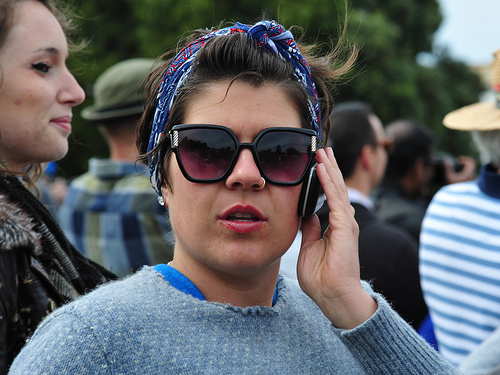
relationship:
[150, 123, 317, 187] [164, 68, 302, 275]
sunglasses on face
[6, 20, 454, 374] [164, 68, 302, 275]
woman has face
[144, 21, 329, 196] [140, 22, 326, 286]
bandana wrapped around head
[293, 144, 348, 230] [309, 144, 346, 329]
cellphone in a woman's hand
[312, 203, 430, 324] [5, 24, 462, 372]
suit coat on man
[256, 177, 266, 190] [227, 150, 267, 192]
nose ring in nose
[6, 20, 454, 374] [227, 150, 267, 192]
woman has nose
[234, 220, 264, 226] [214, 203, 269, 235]
lipstick applied to lips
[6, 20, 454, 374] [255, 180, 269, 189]
woman sporting nose ring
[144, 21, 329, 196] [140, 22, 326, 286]
bandana around head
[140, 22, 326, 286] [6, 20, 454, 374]
head of woman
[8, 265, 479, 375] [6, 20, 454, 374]
sweater on woman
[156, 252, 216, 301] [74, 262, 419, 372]
tshirt under sweater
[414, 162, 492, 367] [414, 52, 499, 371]
shirt on man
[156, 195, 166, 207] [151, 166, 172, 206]
earring on woman's ear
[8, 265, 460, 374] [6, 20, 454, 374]
sweater on woman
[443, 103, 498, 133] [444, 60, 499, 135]
brim of hat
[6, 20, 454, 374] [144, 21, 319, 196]
woman wearing headband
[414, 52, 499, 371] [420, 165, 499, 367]
man wearing shirt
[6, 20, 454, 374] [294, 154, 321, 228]
woman talking on phone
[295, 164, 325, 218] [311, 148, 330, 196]
cellphone on ear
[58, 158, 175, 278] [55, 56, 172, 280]
shirt on a man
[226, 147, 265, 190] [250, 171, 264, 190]
nose ring in her nostril